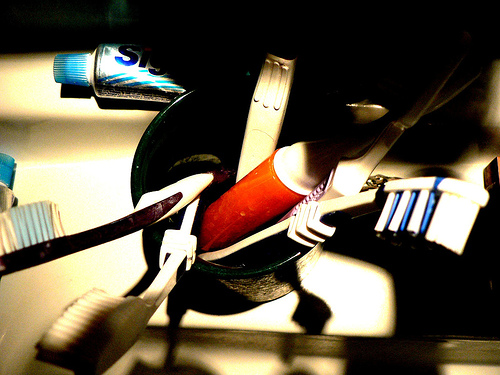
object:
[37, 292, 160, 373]
white toothbrush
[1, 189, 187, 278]
brown toothbrush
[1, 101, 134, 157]
sink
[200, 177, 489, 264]
toothbrush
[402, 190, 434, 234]
bristles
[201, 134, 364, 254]
water pik brush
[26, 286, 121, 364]
white bristles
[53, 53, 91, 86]
blue cap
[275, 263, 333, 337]
shadows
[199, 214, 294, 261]
handle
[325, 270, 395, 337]
light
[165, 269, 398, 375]
shadow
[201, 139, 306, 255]
handle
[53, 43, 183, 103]
toothpaste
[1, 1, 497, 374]
toothbrushes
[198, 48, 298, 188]
electric toothbrush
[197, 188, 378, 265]
white handle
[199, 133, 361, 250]
toothbrush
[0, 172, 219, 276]
toothbrushes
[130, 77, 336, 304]
green cup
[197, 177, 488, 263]
on the toothbrush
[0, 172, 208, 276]
purple toothbrush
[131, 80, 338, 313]
holder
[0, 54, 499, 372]
counter